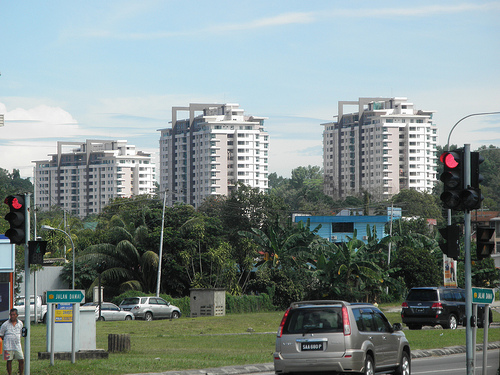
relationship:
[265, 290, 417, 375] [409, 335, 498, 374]
vehicle on road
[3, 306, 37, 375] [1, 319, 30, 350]
person wearing a shirt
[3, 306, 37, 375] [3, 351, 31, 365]
person wearing shorts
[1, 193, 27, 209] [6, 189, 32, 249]
light on traffic light`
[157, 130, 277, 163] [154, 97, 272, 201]
balconies on building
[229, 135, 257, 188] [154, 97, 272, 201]
windows on building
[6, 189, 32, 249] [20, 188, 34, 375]
traffic light` on a pole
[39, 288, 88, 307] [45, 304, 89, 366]
street sign on posts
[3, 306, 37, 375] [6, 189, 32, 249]
person under traffic light`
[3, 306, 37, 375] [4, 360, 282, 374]
person next to street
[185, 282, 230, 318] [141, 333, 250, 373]
transformer box in grass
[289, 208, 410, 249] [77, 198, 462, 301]
structure behind trees